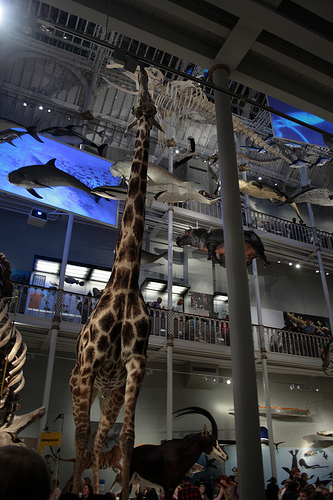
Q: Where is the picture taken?
A: Museum.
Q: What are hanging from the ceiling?
A: Fishes and sharks.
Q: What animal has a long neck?
A: Giraffe.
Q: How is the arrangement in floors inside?
A: Three storied.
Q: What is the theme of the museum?
A: Wildlife.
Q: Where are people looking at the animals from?
A: The balcony.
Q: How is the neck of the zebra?
A: Tall.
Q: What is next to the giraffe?
A: Bone structure.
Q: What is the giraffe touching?
A: A pole.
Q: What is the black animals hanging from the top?
A: Hippo.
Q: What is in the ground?
A: Legs.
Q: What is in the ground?
A: Balconies.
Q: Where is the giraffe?
A: By the metal pole.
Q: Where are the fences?
A: Behind the display.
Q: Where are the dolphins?
A: Above the giraffe.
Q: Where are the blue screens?
A: Behind the animals.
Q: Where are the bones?
A: Hanging in the air.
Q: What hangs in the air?
A: Animals.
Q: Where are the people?
A: Behind the animals.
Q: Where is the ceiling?
A: Above the metal pole.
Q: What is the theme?
A: Animals.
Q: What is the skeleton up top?
A: Shark.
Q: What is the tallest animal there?
A: Giraffe.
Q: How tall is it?
A: Very tall.